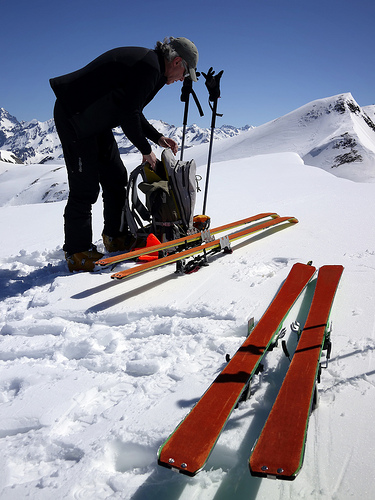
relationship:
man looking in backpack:
[50, 36, 197, 277] [125, 146, 205, 248]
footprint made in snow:
[80, 352, 164, 384] [0, 93, 373, 499]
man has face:
[50, 36, 197, 277] [165, 52, 192, 86]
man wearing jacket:
[50, 36, 197, 277] [49, 39, 167, 154]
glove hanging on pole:
[198, 64, 227, 107] [197, 61, 225, 215]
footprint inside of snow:
[80, 352, 164, 384] [0, 93, 373, 499]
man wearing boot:
[50, 36, 197, 277] [63, 234, 104, 268]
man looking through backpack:
[50, 36, 197, 277] [125, 146, 205, 248]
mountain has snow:
[2, 107, 261, 169] [0, 93, 373, 499]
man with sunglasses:
[50, 36, 197, 277] [179, 63, 192, 82]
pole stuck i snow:
[197, 61, 225, 215] [0, 93, 373, 499]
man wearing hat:
[50, 36, 197, 277] [163, 28, 204, 86]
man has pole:
[50, 36, 197, 277] [197, 61, 225, 215]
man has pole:
[50, 36, 197, 277] [176, 94, 190, 160]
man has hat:
[50, 36, 197, 277] [163, 28, 204, 86]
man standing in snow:
[50, 36, 197, 277] [0, 93, 373, 499]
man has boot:
[50, 36, 197, 277] [63, 234, 104, 268]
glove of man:
[198, 64, 227, 107] [50, 36, 197, 277]